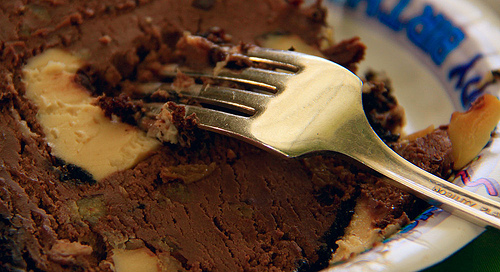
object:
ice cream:
[1, 1, 403, 271]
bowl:
[325, 0, 500, 272]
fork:
[141, 44, 500, 234]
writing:
[348, 0, 466, 66]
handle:
[360, 111, 499, 230]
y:
[446, 54, 484, 90]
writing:
[432, 185, 499, 220]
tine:
[140, 81, 271, 115]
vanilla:
[25, 47, 166, 184]